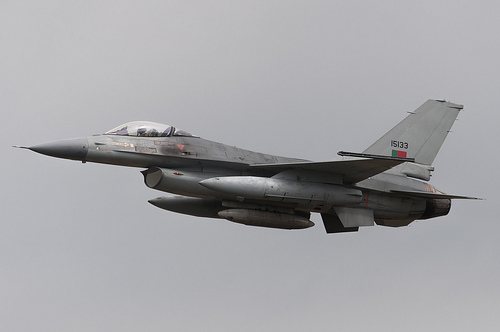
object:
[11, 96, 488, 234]
fighter jet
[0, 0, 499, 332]
sky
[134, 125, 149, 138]
pilot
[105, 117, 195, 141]
cockpit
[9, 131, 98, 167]
nose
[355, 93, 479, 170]
tail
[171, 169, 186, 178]
light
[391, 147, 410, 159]
rectangle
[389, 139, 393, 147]
number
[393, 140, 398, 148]
number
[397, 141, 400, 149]
number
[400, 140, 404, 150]
number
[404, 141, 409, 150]
number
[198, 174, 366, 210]
missile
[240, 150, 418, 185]
wing